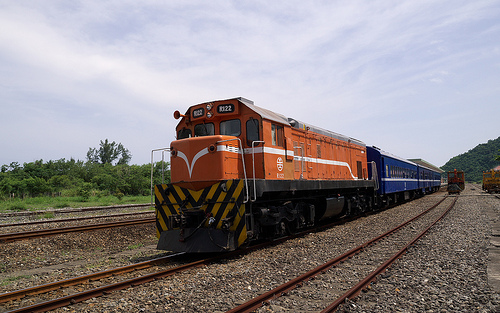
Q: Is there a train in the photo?
A: Yes, there is a train.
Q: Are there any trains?
A: Yes, there is a train.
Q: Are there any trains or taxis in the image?
A: Yes, there is a train.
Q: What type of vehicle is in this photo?
A: The vehicle is a train.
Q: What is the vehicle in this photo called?
A: The vehicle is a train.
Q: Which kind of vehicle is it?
A: The vehicle is a train.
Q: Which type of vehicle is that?
A: That is a train.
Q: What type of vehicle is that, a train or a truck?
A: That is a train.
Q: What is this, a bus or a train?
A: This is a train.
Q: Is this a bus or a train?
A: This is a train.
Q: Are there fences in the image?
A: No, there are no fences.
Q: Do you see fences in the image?
A: No, there are no fences.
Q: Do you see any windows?
A: Yes, there are windows.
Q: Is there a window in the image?
A: Yes, there are windows.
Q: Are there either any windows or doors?
A: Yes, there are windows.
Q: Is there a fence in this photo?
A: No, there are no fences.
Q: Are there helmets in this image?
A: No, there are no helmets.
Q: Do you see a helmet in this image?
A: No, there are no helmets.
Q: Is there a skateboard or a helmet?
A: No, there are no helmets or skateboards.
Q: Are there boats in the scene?
A: No, there are no boats.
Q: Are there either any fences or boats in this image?
A: No, there are no boats or fences.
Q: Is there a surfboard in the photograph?
A: No, there are no surfboards.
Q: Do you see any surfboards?
A: No, there are no surfboards.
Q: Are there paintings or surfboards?
A: No, there are no surfboards or paintings.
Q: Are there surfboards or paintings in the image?
A: No, there are no surfboards or paintings.